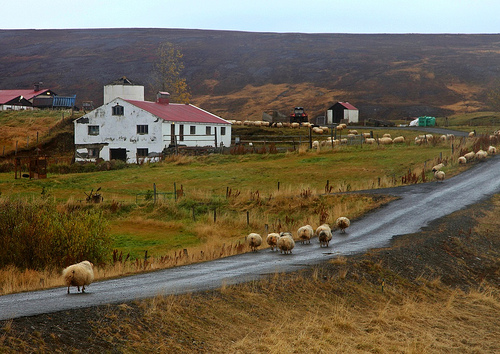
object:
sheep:
[60, 260, 94, 296]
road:
[0, 123, 500, 322]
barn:
[72, 91, 234, 163]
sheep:
[392, 135, 405, 144]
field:
[0, 0, 498, 352]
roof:
[113, 97, 232, 124]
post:
[246, 210, 250, 227]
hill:
[0, 28, 499, 126]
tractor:
[290, 106, 309, 123]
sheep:
[432, 162, 445, 173]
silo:
[101, 83, 144, 103]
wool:
[62, 259, 94, 286]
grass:
[0, 29, 499, 352]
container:
[418, 116, 436, 127]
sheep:
[311, 141, 321, 150]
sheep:
[247, 231, 261, 253]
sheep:
[277, 235, 295, 255]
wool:
[278, 236, 295, 250]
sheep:
[336, 215, 350, 233]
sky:
[0, 0, 499, 33]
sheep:
[348, 128, 359, 136]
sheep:
[297, 224, 314, 244]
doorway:
[108, 147, 127, 162]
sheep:
[266, 232, 280, 252]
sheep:
[318, 229, 333, 247]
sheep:
[377, 137, 393, 145]